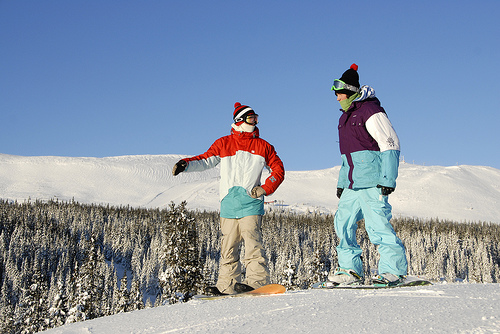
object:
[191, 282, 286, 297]
snow board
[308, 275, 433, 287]
snow board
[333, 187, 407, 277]
pants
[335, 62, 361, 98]
hat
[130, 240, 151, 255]
snow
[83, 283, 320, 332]
white snow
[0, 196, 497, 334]
forest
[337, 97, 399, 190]
jacket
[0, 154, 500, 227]
hills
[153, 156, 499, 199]
white wave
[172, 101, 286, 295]
friend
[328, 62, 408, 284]
friend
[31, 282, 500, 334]
hill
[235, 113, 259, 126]
goggles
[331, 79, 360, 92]
goggles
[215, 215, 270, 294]
trousers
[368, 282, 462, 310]
snow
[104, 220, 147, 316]
water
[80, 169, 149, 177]
ground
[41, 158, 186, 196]
snow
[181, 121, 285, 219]
cloths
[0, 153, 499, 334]
snow hill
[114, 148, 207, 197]
ball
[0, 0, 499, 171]
sky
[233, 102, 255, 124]
hats